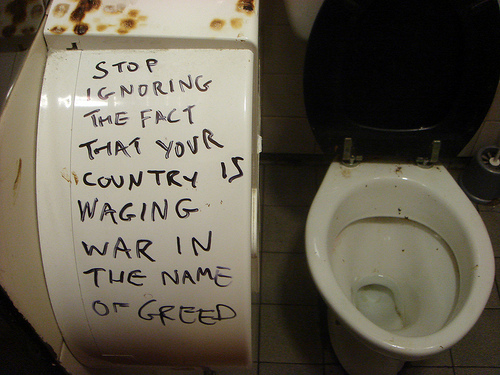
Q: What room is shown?
A: It is a bathroom.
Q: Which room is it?
A: It is a bathroom.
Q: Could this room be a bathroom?
A: Yes, it is a bathroom.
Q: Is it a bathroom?
A: Yes, it is a bathroom.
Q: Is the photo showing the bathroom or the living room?
A: It is showing the bathroom.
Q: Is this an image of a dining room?
A: No, the picture is showing a bathroom.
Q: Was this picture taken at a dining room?
A: No, the picture was taken in a bathroom.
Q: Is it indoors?
A: Yes, it is indoors.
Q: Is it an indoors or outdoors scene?
A: It is indoors.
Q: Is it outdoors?
A: No, it is indoors.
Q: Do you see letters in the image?
A: Yes, there are letters.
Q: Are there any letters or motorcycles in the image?
A: Yes, there are letters.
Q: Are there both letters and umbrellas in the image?
A: No, there are letters but no umbrellas.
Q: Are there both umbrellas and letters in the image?
A: No, there are letters but no umbrellas.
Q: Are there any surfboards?
A: No, there are no surfboards.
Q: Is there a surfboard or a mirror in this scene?
A: No, there are no surfboards or mirrors.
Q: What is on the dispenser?
A: The letters are on the dispenser.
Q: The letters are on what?
A: The letters are on the dispenser.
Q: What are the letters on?
A: The letters are on the dispenser.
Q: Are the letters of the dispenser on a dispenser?
A: Yes, the letters are on a dispenser.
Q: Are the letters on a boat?
A: No, the letters are on a dispenser.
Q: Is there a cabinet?
A: No, there are no cabinets.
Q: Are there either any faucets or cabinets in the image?
A: No, there are no cabinets or faucets.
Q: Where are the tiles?
A: The tiles are on the floor.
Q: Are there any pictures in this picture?
A: No, there are no pictures.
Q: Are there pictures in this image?
A: No, there are no pictures.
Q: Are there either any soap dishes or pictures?
A: No, there are no pictures or soap dishes.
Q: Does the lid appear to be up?
A: Yes, the lid is up.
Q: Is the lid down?
A: No, the lid is up.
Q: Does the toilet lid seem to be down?
A: No, the lid is up.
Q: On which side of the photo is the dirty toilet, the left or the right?
A: The toilet is on the right of the image.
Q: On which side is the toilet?
A: The toilet is on the right of the image.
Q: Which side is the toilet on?
A: The toilet is on the right of the image.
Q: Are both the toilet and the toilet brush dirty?
A: Yes, both the toilet and the toilet brush are dirty.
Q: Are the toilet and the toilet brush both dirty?
A: Yes, both the toilet and the toilet brush are dirty.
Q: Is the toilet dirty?
A: Yes, the toilet is dirty.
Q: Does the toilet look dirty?
A: Yes, the toilet is dirty.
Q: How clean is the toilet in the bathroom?
A: The toilet is dirty.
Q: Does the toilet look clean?
A: No, the toilet is dirty.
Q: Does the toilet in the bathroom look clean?
A: No, the toilet is dirty.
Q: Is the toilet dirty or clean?
A: The toilet is dirty.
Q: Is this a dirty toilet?
A: Yes, this is a dirty toilet.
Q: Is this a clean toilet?
A: No, this is a dirty toilet.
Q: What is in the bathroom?
A: The toilet is in the bathroom.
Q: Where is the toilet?
A: The toilet is in the bathroom.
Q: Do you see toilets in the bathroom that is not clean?
A: Yes, there is a toilet in the bathroom.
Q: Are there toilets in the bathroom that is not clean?
A: Yes, there is a toilet in the bathroom.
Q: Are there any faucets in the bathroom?
A: No, there is a toilet in the bathroom.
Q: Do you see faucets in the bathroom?
A: No, there is a toilet in the bathroom.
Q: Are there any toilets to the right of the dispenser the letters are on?
A: Yes, there is a toilet to the right of the dispenser.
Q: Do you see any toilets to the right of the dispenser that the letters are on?
A: Yes, there is a toilet to the right of the dispenser.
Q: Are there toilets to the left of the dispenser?
A: No, the toilet is to the right of the dispenser.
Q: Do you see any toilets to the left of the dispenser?
A: No, the toilet is to the right of the dispenser.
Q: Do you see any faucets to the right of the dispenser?
A: No, there is a toilet to the right of the dispenser.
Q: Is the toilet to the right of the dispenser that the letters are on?
A: Yes, the toilet is to the right of the dispenser.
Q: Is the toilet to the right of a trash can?
A: No, the toilet is to the right of the dispenser.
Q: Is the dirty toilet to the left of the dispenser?
A: No, the toilet is to the right of the dispenser.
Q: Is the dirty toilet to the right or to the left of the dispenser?
A: The toilet is to the right of the dispenser.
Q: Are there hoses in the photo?
A: No, there are no hoses.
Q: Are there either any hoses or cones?
A: No, there are no hoses or cones.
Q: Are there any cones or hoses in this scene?
A: No, there are no hoses or cones.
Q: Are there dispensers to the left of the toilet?
A: Yes, there is a dispenser to the left of the toilet.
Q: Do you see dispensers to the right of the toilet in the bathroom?
A: No, the dispenser is to the left of the toilet.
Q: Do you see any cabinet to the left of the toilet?
A: No, there is a dispenser to the left of the toilet.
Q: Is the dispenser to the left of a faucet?
A: No, the dispenser is to the left of the toilet.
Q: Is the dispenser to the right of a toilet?
A: No, the dispenser is to the left of a toilet.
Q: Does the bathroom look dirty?
A: Yes, the bathroom is dirty.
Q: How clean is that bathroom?
A: The bathroom is dirty.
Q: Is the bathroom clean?
A: No, the bathroom is dirty.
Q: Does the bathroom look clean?
A: No, the bathroom is dirty.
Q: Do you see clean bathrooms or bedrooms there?
A: No, there is a bathroom but it is dirty.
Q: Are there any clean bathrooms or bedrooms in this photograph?
A: No, there is a bathroom but it is dirty.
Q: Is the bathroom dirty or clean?
A: The bathroom is dirty.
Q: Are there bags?
A: No, there are no bags.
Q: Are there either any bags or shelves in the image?
A: No, there are no bags or shelves.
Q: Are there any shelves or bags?
A: No, there are no bags or shelves.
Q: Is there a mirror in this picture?
A: No, there are no mirrors.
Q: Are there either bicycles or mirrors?
A: No, there are no mirrors or bicycles.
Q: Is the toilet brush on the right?
A: Yes, the toilet brush is on the right of the image.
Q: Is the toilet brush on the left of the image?
A: No, the toilet brush is on the right of the image.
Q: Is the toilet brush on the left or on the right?
A: The toilet brush is on the right of the image.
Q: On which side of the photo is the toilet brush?
A: The toilet brush is on the right of the image.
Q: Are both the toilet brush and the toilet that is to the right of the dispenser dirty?
A: Yes, both the toilet brush and the toilet are dirty.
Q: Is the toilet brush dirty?
A: Yes, the toilet brush is dirty.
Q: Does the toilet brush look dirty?
A: Yes, the toilet brush is dirty.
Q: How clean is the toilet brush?
A: The toilet brush is dirty.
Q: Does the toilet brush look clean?
A: No, the toilet brush is dirty.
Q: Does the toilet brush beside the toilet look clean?
A: No, the toilet brush is dirty.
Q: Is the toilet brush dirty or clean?
A: The toilet brush is dirty.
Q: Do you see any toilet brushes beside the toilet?
A: Yes, there is a toilet brush beside the toilet.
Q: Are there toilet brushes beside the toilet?
A: Yes, there is a toilet brush beside the toilet.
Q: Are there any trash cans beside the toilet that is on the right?
A: No, there is a toilet brush beside the toilet.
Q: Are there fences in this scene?
A: No, there are no fences.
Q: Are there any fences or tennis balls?
A: No, there are no fences or tennis balls.